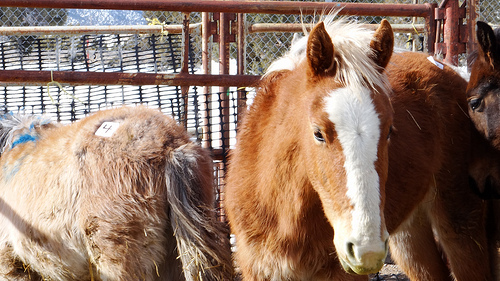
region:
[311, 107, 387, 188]
This horse has very black eyes that are visible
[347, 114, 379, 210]
This horse has a bright white patch here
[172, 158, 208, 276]
This animal has a very fluffy tail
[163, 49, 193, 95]
There is a rusty fence that is visible here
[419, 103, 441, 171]
There is a bright spot of brown on this horse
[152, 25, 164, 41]
There is a rusty section of pipe here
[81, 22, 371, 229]
This was taken in the state of Montana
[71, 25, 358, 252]
This was taken in the season of winter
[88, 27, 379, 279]
Jackson Mingus took this photo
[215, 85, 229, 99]
part of a rail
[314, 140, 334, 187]
eye of a horse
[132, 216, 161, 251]
back of a leg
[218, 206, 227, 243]
part of a tail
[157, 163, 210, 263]
edge of a tail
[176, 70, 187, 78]
part of a rail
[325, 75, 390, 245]
a white spot on the horse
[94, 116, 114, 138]
the number 4 on the horse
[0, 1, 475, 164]
a gate behind the horse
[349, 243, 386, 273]
a brown tip on the horse's nose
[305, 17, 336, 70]
the horse has a right ear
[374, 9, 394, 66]
the horse has a left ear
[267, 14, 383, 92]
the horse has a white mane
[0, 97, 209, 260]
this horse has shaggy fur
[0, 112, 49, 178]
blue spots on the horse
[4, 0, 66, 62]
a tree behind the gate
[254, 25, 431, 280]
this is a horse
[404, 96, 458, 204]
the horse is brown in color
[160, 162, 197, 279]
this is the tail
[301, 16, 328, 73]
this is the ear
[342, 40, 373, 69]
this is the fur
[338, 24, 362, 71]
the fur is white in color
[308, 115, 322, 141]
this is the eye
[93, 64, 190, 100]
this is a pole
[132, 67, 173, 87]
the pole is metallic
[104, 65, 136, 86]
the pole has rusted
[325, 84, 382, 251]
White strip of fur on a horses nose.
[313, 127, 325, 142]
Black eye of a brown and white horse.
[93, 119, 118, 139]
A white shaved spot with the number 4 on it.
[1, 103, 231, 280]
A fluffy soft looking pony with grey tail.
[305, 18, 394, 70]
Two brown ears on a brown and white horse.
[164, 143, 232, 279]
A grey and tan looking pony tail.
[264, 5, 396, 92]
White horse main on a brown and white horse.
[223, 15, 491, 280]
A brown and white horse with it's eyes open.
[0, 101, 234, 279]
A light brown and white pony with the number 4 on it.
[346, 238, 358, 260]
A right side nostril of a horse.